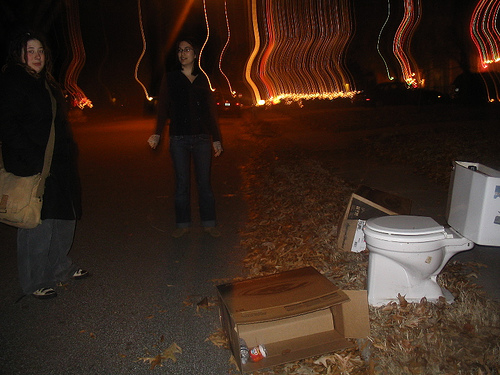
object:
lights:
[59, 0, 497, 110]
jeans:
[170, 146, 216, 229]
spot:
[424, 254, 434, 268]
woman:
[146, 30, 226, 237]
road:
[0, 100, 246, 363]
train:
[140, 33, 227, 233]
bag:
[0, 71, 58, 230]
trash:
[215, 266, 375, 372]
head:
[175, 42, 196, 66]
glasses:
[176, 47, 196, 52]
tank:
[448, 160, 499, 246]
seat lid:
[365, 214, 443, 237]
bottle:
[240, 338, 248, 370]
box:
[214, 265, 371, 373]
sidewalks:
[219, 104, 494, 375]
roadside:
[236, 113, 500, 375]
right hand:
[145, 132, 160, 150]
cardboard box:
[216, 266, 372, 375]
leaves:
[380, 339, 456, 373]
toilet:
[357, 164, 500, 311]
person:
[0, 33, 94, 300]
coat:
[1, 70, 86, 221]